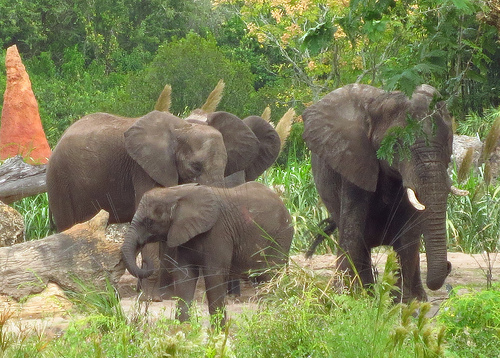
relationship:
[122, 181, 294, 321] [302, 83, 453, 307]
baby and elephant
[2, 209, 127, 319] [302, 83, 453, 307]
log by elephant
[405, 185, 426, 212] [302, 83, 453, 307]
tusk on elephant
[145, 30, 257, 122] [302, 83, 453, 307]
tree behind elephant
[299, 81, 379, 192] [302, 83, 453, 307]
ear on elephant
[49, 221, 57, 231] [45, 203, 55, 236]
tuft on tail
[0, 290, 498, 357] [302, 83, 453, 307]
grass by elephant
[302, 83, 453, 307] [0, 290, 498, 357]
elephant by grass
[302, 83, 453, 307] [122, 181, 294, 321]
elephant and baby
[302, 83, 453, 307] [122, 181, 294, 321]
elephant by baby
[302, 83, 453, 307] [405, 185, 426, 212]
elephant os tusk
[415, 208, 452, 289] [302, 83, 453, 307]
trunk on elephant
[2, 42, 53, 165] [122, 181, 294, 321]
cone behind baby